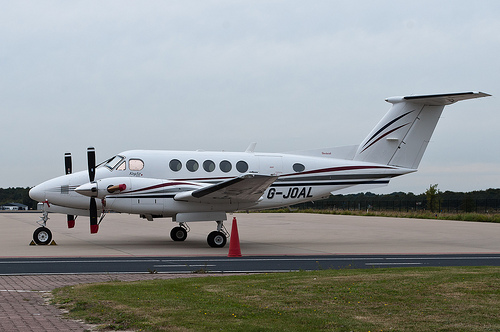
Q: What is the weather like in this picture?
A: It is cloudy.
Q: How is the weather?
A: It is cloudy.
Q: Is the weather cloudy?
A: Yes, it is cloudy.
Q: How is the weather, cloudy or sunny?
A: It is cloudy.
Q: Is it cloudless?
A: No, it is cloudy.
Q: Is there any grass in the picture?
A: Yes, there is grass.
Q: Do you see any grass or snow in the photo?
A: Yes, there is grass.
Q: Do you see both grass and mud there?
A: No, there is grass but no mud.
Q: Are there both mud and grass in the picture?
A: No, there is grass but no mud.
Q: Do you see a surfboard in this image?
A: No, there are no surfboards.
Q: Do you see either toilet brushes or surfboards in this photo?
A: No, there are no surfboards or toilet brushes.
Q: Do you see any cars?
A: No, there are no cars.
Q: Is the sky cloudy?
A: Yes, the sky is cloudy.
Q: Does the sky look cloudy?
A: Yes, the sky is cloudy.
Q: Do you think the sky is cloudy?
A: Yes, the sky is cloudy.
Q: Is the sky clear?
A: No, the sky is cloudy.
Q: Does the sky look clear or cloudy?
A: The sky is cloudy.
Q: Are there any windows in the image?
A: Yes, there is a window.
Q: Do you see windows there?
A: Yes, there is a window.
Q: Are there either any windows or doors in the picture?
A: Yes, there is a window.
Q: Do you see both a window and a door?
A: No, there is a window but no doors.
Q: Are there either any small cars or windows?
A: Yes, there is a small window.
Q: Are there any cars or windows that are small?
A: Yes, the window is small.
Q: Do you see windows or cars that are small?
A: Yes, the window is small.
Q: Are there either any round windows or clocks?
A: Yes, there is a round window.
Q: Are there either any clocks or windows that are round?
A: Yes, the window is round.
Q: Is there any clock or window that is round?
A: Yes, the window is round.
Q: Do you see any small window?
A: Yes, there is a small window.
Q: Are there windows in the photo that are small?
A: Yes, there is a window that is small.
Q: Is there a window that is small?
A: Yes, there is a window that is small.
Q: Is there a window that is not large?
A: Yes, there is a small window.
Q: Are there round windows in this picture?
A: Yes, there is a round window.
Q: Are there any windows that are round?
A: Yes, there is a window that is round.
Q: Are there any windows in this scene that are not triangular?
A: Yes, there is a round window.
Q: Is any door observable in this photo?
A: No, there are no doors.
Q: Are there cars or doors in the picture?
A: No, there are no doors or cars.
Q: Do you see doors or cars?
A: No, there are no doors or cars.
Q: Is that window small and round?
A: Yes, the window is small and round.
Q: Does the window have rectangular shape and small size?
A: No, the window is small but round.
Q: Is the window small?
A: Yes, the window is small.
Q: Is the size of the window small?
A: Yes, the window is small.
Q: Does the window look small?
A: Yes, the window is small.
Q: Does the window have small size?
A: Yes, the window is small.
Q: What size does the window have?
A: The window has small size.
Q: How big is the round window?
A: The window is small.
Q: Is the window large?
A: No, the window is small.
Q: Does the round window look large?
A: No, the window is small.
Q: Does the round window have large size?
A: No, the window is small.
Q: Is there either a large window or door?
A: No, there is a window but it is small.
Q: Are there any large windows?
A: No, there is a window but it is small.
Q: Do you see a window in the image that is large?
A: No, there is a window but it is small.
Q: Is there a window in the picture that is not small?
A: No, there is a window but it is small.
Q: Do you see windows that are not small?
A: No, there is a window but it is small.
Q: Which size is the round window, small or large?
A: The window is small.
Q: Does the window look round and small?
A: Yes, the window is round and small.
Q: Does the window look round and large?
A: No, the window is round but small.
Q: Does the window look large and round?
A: No, the window is round but small.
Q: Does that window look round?
A: Yes, the window is round.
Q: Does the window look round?
A: Yes, the window is round.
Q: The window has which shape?
A: The window is round.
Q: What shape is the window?
A: The window is round.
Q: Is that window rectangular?
A: No, the window is round.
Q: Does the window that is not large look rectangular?
A: No, the window is round.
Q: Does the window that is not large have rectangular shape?
A: No, the window is round.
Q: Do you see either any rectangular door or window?
A: No, there is a window but it is round.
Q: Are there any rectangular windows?
A: No, there is a window but it is round.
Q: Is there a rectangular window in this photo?
A: No, there is a window but it is round.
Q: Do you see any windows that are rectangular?
A: No, there is a window but it is round.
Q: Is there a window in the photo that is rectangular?
A: No, there is a window but it is round.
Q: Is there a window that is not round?
A: No, there is a window but it is round.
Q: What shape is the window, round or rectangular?
A: The window is round.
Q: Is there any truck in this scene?
A: No, there are no trucks.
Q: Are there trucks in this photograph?
A: No, there are no trucks.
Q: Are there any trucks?
A: No, there are no trucks.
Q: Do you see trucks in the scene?
A: No, there are no trucks.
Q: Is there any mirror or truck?
A: No, there are no trucks or mirrors.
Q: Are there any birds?
A: No, there are no birds.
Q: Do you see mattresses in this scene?
A: No, there are no mattresses.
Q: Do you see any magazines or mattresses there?
A: No, there are no mattresses or magazines.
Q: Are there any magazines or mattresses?
A: No, there are no mattresses or magazines.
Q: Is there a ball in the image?
A: No, there are no balls.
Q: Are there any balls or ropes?
A: No, there are no balls or ropes.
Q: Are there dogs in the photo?
A: No, there are no dogs.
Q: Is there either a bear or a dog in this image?
A: No, there are no dogs or bears.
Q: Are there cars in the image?
A: No, there are no cars.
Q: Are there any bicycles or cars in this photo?
A: No, there are no cars or bicycles.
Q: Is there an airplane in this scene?
A: Yes, there is an airplane.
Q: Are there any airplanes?
A: Yes, there is an airplane.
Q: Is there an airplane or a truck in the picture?
A: Yes, there is an airplane.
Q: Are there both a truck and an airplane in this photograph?
A: No, there is an airplane but no trucks.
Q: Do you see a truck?
A: No, there are no trucks.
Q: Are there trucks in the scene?
A: No, there are no trucks.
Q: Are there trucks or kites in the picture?
A: No, there are no trucks or kites.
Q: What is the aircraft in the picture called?
A: The aircraft is an airplane.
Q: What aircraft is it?
A: The aircraft is an airplane.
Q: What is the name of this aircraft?
A: This is an airplane.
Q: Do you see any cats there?
A: No, there are no cats.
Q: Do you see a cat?
A: No, there are no cats.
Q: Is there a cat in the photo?
A: No, there are no cats.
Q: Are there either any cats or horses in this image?
A: No, there are no cats or horses.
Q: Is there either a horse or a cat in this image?
A: No, there are no cats or horses.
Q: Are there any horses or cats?
A: No, there are no cats or horses.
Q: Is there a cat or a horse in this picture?
A: No, there are no cats or horses.